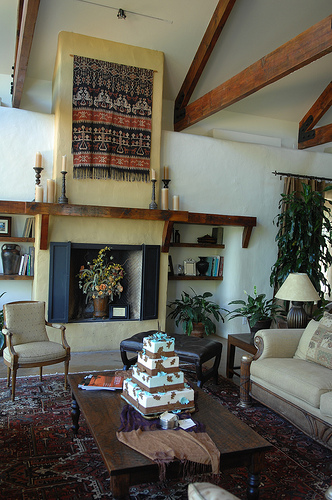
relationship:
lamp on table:
[275, 271, 320, 328] [226, 327, 305, 401]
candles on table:
[31, 144, 183, 213] [0, 197, 256, 250]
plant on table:
[228, 287, 290, 343] [224, 329, 285, 384]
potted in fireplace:
[89, 290, 114, 315] [44, 212, 164, 320]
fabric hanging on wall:
[69, 51, 157, 184] [55, 31, 166, 207]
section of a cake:
[143, 332, 176, 359] [117, 327, 195, 421]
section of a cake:
[137, 351, 179, 373] [117, 327, 195, 421]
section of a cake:
[117, 383, 196, 413] [117, 327, 195, 421]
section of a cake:
[140, 333, 179, 354] [117, 327, 195, 421]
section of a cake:
[137, 351, 179, 373] [120, 328, 194, 409]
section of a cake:
[129, 354, 185, 390] [120, 328, 194, 409]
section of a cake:
[121, 383, 196, 419] [118, 330, 194, 416]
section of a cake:
[140, 330, 178, 358] [120, 328, 194, 409]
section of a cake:
[129, 354, 185, 390] [118, 330, 194, 416]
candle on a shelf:
[147, 164, 159, 211] [7, 197, 258, 227]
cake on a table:
[117, 327, 195, 421] [62, 360, 270, 470]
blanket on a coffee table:
[113, 404, 223, 478] [67, 370, 273, 499]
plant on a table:
[165, 285, 230, 335] [179, 333, 221, 340]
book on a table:
[76, 368, 124, 393] [62, 360, 270, 470]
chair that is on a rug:
[2, 292, 72, 403] [13, 363, 230, 484]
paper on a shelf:
[108, 305, 128, 321] [47, 318, 162, 349]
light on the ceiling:
[114, 7, 129, 25] [31, 10, 188, 84]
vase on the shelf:
[197, 254, 212, 276] [169, 274, 225, 279]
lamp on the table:
[274, 272, 321, 328] [223, 333, 300, 381]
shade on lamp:
[271, 269, 325, 307] [273, 272, 324, 331]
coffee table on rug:
[67, 370, 273, 499] [1, 356, 328, 497]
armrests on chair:
[0, 329, 16, 354] [0, 298, 72, 399]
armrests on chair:
[43, 318, 71, 351] [0, 298, 72, 399]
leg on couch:
[236, 355, 254, 408] [230, 316, 330, 451]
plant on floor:
[165, 289, 230, 341] [0, 342, 330, 498]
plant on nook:
[165, 289, 230, 341] [160, 220, 231, 366]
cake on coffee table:
[120, 330, 196, 420] [67, 370, 273, 499]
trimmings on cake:
[147, 330, 168, 344] [120, 330, 196, 420]